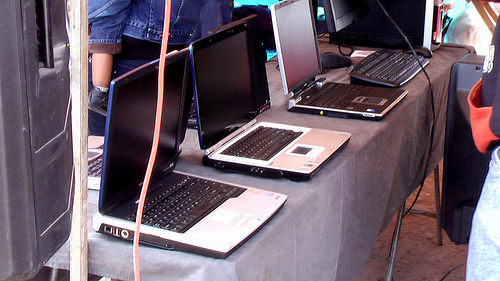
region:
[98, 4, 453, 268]
Laptops displayed on a table.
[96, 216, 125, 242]
A USB port on the laptop's side.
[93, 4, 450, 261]
Four opened laptops.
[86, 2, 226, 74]
Person behind wearing a denim top.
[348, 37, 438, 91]
A computer keyboard.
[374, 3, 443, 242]
A computer wire.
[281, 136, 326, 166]
The mousepad.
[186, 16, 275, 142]
Laptop screen.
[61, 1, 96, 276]
A white slender post.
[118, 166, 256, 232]
The laptop keyboard has black buttons.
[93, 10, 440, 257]
Laptops are seen.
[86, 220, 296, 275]
grey color table.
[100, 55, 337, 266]
laptops are kept in the table.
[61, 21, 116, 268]
brown color pole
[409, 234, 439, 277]
brown color mud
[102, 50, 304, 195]
monitors are off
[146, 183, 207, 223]
black color keypad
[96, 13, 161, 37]
blue color coat.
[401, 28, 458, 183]
black color wire is hanging down.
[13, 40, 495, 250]
The picture is taken in the daytime.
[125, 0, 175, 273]
electrical cord hanging down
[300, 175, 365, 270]
whitish colored tablecloth on table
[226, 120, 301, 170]
a keyboard on a laptop computer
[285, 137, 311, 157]
a trackpad on a laptop computer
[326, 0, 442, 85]
desktop computer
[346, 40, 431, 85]
full size black keyboard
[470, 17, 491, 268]
person with blue jeans on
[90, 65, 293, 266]
lap top computer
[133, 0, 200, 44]
blue jean denim jacket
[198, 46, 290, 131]
computer monitor of a laptop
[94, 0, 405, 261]
Three laptops with black keyboards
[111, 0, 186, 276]
An orange cable hangs by the laptop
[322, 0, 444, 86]
The computer in the back is a desktop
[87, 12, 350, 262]
Two laptops have white bases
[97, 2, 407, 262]
Three laptops with black screens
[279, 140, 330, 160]
The trackpad is black with a white frame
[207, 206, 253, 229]
The trackpad is white with two white buttons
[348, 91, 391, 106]
The trackpad is black with a silver frame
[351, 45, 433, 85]
The keyboard in the back is black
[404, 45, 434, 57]
The mouse in the back is black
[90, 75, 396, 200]
laptops are on table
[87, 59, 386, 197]
the laptops are open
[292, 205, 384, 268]
the table cloth is gray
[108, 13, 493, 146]
three laptops on the table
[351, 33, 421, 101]
the keyboard is black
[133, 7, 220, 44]
the jacket is denim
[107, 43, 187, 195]
the monitor is black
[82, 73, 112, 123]
the shoe is black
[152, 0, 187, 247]
the wire is orange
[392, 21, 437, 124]
the wire is black